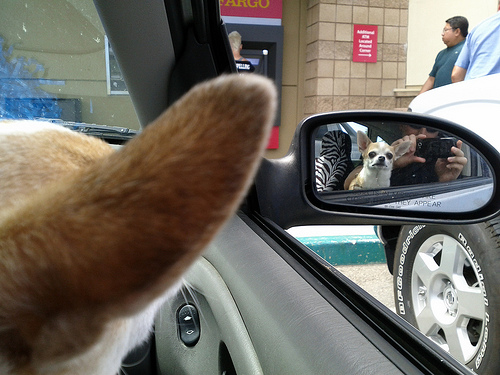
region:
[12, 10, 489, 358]
a dog waiting in a car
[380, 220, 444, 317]
the bfgoodrich logo on a tire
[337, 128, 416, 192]
a chihuahua checking his reflection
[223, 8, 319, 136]
a wells fargo atm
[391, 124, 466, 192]
a woman taking a picture of her dog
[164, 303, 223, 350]
the window control in a car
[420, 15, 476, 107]
a man waiting for the atm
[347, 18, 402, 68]
a red sign indicating where to line up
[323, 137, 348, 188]
a zebra printed seat cover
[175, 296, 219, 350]
A black button to roll on the inside of a car door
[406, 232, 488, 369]
A silver tire rim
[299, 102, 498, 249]
A reflection of a dog in a side mirror on a vehicle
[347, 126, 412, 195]
A brown and white dog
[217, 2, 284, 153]
A Wells Fargo ATM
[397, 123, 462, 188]
A person taking a picture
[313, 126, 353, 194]
A zebra printed car seat cover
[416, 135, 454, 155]
A black cell phone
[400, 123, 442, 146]
A person wearing black sunglasses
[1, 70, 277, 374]
The back of a chihuahua's right ear and head.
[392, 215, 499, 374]
A black tire with white writing on it.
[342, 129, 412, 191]
Brown and white chihuahua in the rear view mirror.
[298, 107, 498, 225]
Passenger side rear view mirror with a dog and person in it.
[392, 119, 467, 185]
Man in a rear view mirror with glasses on taking a picture.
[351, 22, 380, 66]
Red sign on a wall with white writing.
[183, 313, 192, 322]
White up arrow for the door window.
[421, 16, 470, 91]
A black haired man in a blue shirt standing by a red sign.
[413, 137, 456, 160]
A black phone being held sideways.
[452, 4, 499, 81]
A man turned around backwards in a blue shirt.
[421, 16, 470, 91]
man is wearing eye glasses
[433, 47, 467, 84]
man's shirt is green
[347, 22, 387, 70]
red sign on wall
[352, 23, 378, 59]
white letters on sign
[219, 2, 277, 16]
yellow letters on sign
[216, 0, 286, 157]
person standing in front of atm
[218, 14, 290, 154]
atm is black and red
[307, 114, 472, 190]
person taking a picture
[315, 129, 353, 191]
chair is zebra printed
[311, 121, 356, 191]
The car seat has a zebra print cover.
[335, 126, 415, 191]
The dog is looking in the mirror.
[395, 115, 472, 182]
The person is taking a picture.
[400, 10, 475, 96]
The man is in a blue shirt.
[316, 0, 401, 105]
A red sign is on a brick wall.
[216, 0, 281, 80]
A person is using an ATM machine.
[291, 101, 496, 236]
In the mirror, is a reflection of a dog and a person.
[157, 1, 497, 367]
The window is down in the car.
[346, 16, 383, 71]
The lettering is white on the red sign.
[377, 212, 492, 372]
The black tire has white lettering and silver rims.